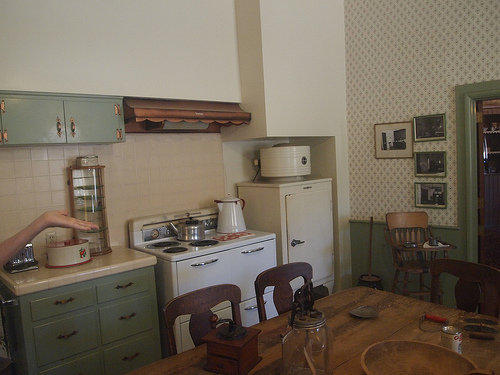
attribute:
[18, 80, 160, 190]
cabinets — green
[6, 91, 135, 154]
cabinets — gray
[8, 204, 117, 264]
hand — white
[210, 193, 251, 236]
percolator — white, red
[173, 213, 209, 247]
teapot — metal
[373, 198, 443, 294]
highchair — wooden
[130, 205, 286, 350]
stove — white, old fashioned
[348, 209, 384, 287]
butter churn — wooden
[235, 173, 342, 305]
ice box — old fashioned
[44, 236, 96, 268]
cover — red, white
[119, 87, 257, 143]
hood — brown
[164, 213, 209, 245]
kettle — silver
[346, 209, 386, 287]
butter churn — brown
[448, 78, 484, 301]
door frame — green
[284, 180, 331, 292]
door — white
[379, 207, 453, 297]
high chair — brown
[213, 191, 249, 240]
kettle — white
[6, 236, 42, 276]
toaster — silver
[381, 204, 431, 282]
highchair — wooden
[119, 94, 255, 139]
fan hood — cooper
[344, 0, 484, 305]
wall — checkered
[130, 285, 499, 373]
table — kitchen table